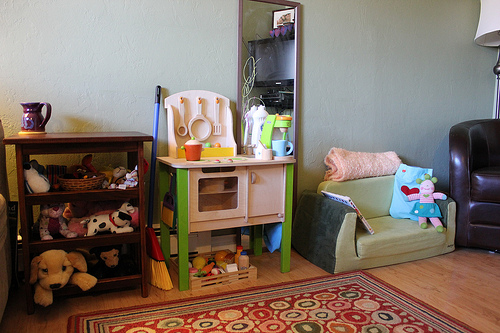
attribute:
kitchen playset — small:
[155, 89, 298, 290]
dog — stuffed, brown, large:
[26, 248, 97, 310]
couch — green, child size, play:
[292, 172, 456, 275]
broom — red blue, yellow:
[144, 84, 173, 290]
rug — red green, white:
[66, 268, 483, 331]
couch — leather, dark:
[448, 115, 499, 257]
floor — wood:
[1, 245, 499, 331]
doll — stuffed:
[404, 172, 448, 232]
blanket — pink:
[321, 145, 401, 180]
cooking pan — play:
[188, 96, 211, 143]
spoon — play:
[176, 93, 187, 139]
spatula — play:
[211, 94, 222, 139]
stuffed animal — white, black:
[81, 201, 137, 236]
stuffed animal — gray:
[32, 198, 76, 240]